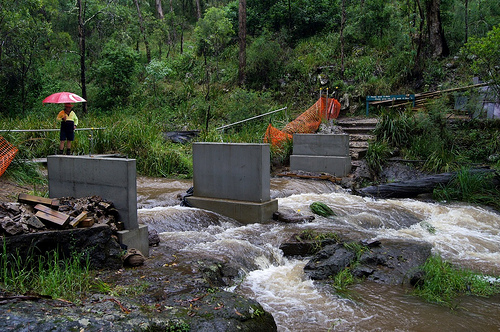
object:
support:
[287, 133, 353, 176]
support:
[184, 140, 280, 224]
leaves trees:
[49, 0, 134, 115]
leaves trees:
[215, 0, 279, 89]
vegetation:
[0, 0, 500, 203]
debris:
[97, 201, 112, 210]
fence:
[265, 97, 341, 148]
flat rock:
[0, 263, 282, 332]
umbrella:
[42, 92, 88, 105]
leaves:
[221, 68, 225, 72]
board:
[0, 223, 111, 244]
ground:
[1, 248, 272, 332]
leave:
[403, 33, 405, 35]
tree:
[131, 0, 153, 67]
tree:
[463, 0, 470, 47]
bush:
[7, 57, 471, 152]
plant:
[116, 120, 158, 155]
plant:
[364, 135, 394, 172]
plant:
[430, 180, 461, 203]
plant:
[370, 105, 416, 144]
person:
[55, 103, 79, 155]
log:
[358, 165, 496, 198]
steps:
[333, 121, 378, 128]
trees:
[229, 0, 256, 88]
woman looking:
[55, 103, 79, 155]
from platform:
[44, 152, 152, 253]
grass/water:
[255, 208, 500, 331]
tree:
[230, 0, 256, 92]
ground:
[299, 102, 496, 193]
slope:
[0, 0, 500, 177]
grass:
[408, 251, 500, 311]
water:
[49, 164, 500, 332]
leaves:
[409, 21, 412, 24]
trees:
[61, 0, 111, 118]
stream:
[32, 161, 500, 332]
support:
[47, 152, 149, 253]